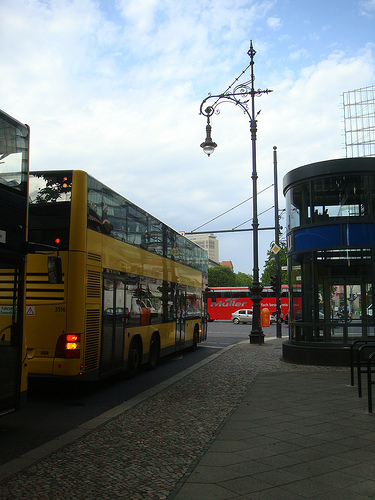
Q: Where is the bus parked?
A: Next to the light post.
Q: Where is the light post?
A: Sidewalk.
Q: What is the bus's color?
A: Yellow.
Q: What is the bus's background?
A: Red.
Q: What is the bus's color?
A: Yellow.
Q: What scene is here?
A: Downtown.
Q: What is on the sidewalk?
A: Cobble stone.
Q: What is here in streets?
A: Buses.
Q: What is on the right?
A: Bus station.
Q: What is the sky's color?
A: Blue.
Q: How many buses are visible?
A: Two.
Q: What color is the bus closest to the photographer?
A: Yellow.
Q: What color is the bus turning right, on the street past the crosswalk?
A: Red.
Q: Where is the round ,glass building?
A: On the right, on the sidewalk, behind the lamppost.